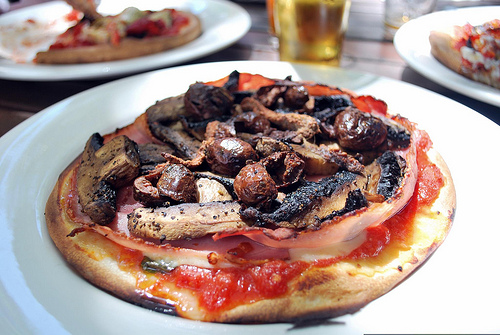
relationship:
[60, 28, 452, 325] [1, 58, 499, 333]
pizza on plate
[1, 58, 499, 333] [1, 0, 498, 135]
plate on table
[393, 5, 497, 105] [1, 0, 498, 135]
plate on table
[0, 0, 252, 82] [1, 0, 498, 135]
plate on table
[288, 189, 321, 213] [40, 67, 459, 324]
black decoration on pizza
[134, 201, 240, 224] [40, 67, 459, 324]
cumin on pizza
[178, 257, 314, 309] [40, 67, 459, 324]
sauce on pizza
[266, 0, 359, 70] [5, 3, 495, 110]
glass on table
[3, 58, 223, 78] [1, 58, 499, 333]
rim on plate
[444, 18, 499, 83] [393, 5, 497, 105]
pizza on plate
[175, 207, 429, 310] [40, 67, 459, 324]
red sauce on pizza